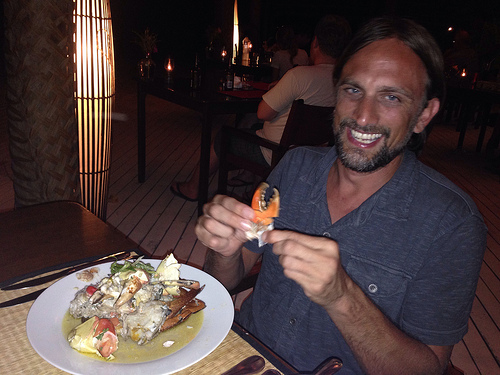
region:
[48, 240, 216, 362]
seafood on white plate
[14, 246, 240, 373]
white plate on table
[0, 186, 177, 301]
a black folder on table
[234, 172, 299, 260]
man holding a lobster claw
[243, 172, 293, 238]
orange and red lobster claw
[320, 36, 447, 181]
man smiling at camera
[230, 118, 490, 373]
man wearing a dark blue shirt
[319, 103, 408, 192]
man with a beard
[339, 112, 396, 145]
man with a moustache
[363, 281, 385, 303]
button on man's shirt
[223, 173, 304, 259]
a man is holding a crab claw.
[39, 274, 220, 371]
A plate of food is on the table.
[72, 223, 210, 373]
Seafood is displayed on a white plate.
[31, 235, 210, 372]
a white plate of seafood is on the table.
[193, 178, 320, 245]
A crab claw is being help by a man.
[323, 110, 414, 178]
a man is smiling.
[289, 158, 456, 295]
A man is wearing a blue shirt.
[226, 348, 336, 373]
Silver utenils is on the table.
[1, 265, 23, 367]
A place mat is on the table.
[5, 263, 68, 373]
a place mat is under a white plate.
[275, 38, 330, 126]
A man sitting in the background.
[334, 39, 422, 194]
A man smiling at the camera.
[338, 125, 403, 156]
Smile of the man.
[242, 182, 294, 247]
Lobster in a man's hands.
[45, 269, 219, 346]
A meal being eaten by a man.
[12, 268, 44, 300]
Eating utensils on a table.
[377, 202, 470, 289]
Blue collared shirt being worn by the man.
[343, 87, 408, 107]
Eyes of the man.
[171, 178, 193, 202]
Sandals of a man.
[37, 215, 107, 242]
A table being used for a meal.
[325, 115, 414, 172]
a man's gray and black beard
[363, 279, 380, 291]
a small shirt button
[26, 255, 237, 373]
a large white plate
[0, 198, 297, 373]
part of a brown table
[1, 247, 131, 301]
a silver knife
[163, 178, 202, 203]
a man's sandal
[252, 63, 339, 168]
part of a man's white shirt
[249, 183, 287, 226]
a small crab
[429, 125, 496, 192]
part of a wooden floor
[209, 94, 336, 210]
part of a chair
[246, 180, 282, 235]
cooked orange crustacean claw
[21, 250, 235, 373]
big white plate of seafood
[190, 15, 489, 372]
man eating seafood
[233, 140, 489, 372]
dark blue collared shirt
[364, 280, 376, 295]
shiny dark blue button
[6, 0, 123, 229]
rattan wicker lantern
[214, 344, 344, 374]
handles of a few pieces of silver ware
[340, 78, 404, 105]
blue eyes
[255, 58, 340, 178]
white tee shirt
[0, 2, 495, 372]
a crowded restaurant